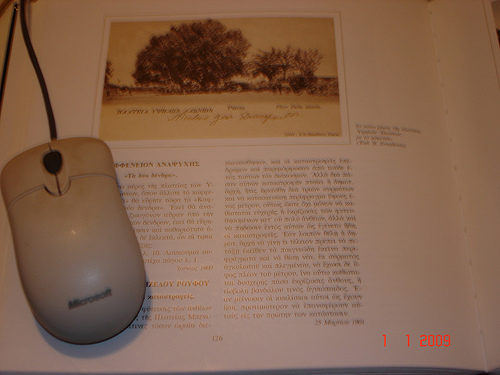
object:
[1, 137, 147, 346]
mouse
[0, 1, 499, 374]
book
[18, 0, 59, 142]
wire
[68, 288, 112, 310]
word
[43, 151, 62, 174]
scroll wheel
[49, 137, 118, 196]
button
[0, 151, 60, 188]
button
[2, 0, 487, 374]
page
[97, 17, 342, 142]
picture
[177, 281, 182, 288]
letter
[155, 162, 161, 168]
letter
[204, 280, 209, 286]
letter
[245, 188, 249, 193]
letter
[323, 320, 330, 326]
letter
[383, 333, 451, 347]
date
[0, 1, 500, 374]
picture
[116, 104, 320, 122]
writing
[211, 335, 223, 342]
page number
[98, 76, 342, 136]
field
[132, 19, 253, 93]
tree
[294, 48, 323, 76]
tree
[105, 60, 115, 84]
tree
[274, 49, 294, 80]
tree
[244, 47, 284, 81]
tree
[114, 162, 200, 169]
title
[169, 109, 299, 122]
handwriting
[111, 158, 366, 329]
text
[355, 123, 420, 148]
caption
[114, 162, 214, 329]
column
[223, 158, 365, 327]
column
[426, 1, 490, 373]
binding